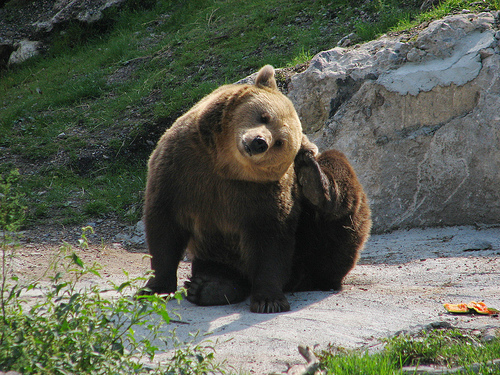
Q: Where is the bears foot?
A: In his ear.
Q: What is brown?
A: Bear.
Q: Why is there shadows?
A: Sunlight.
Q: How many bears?
A: One.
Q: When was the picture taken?
A: Daytime.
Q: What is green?
A: Grass.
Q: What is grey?
A: Rocks.